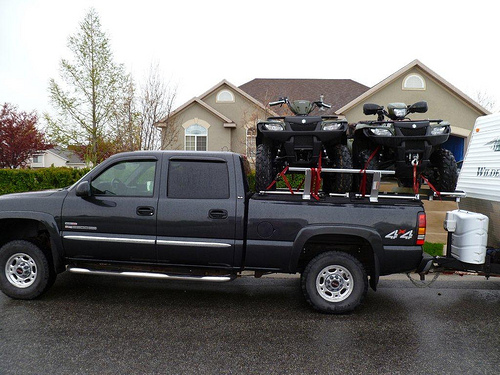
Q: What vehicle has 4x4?
A: A pickup.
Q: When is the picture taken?
A: Daytime.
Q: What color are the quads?
A: Black.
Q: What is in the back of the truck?
A: Two quads.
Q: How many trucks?
A: One.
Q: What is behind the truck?
A: A camper.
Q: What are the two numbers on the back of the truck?
A: Fours.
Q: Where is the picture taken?
A: Subdivision.